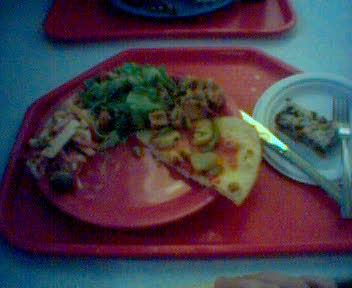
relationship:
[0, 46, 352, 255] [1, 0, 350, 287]
tray on table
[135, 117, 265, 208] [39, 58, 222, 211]
food on plate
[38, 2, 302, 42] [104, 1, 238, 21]
lunch tray with plate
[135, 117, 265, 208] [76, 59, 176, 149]
food with leaves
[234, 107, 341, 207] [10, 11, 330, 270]
knief in table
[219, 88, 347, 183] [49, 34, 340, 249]
knief on plate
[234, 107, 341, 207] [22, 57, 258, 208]
knief beside food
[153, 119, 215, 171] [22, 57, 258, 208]
decoration on food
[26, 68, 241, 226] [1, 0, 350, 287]
plate in table